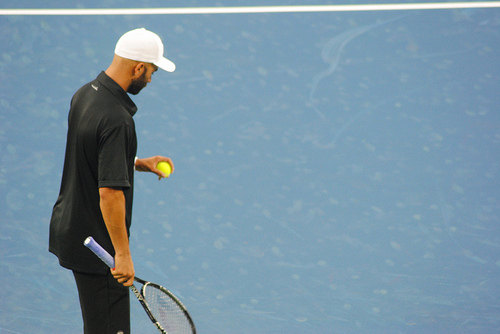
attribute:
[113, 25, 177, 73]
hat — white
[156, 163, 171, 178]
ball — yellow, round, green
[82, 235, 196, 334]
racket — blue, black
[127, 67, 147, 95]
beard — black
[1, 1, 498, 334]
background — blue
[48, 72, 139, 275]
shirt — black, black cotton polo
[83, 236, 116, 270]
handle — light blue, purple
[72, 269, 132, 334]
tennis shorts — black cotton, black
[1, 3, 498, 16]
line — white